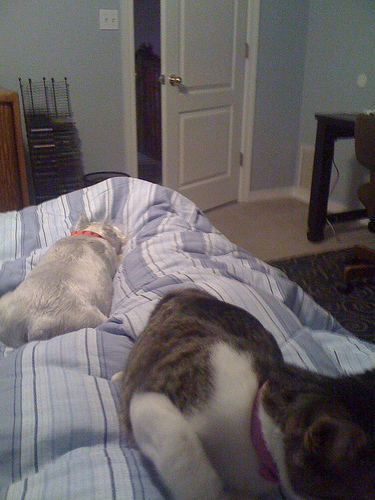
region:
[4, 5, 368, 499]
Interior view, season, not known.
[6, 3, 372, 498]
Room interior, likely daytime, with natural light.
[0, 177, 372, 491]
Bedding with striped coverlet.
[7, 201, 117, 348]
Reclining light grey and white cat.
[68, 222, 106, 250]
Pink collar on cat.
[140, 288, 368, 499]
Prone dark grey and white cat.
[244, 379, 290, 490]
Lavender collar on cat.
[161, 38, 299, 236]
Blue wall, next to white door and baseboard with vent.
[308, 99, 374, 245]
Small balck table, with chair and electrical cord.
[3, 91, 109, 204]
Part of wood furnishing and metal rack with items on it.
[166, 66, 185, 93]
gld colored door knob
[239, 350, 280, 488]
purple collar on a cat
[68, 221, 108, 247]
orange collar on a cat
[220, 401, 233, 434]
white fur ona cat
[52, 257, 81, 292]
grey fur on a cat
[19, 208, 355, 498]
two cats laying on the bed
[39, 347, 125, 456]
blue striped bed spread cover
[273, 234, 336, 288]
area rug on the bedroom floor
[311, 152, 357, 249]
wires by a night stand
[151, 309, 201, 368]
back of a tabby cat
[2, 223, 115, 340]
a cat on the bed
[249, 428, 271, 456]
a purple collar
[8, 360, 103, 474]
the comforter is blue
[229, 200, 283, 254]
the carpet is brown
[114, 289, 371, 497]
the cat is grey and white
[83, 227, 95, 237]
a black and red collar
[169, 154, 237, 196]
a white door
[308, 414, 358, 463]
ear on the cat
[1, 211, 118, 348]
the cat is lying on the bed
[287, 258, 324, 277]
a rug on the floor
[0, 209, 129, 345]
a dog laying on a bed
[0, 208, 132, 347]
a dog sleeping on a blanket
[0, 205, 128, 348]
a dog with a red and black collar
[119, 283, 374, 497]
a cat laying on a blanket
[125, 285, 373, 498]
a cat sleeping on a bed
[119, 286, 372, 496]
a cat with a purple collar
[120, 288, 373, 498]
a black and white cat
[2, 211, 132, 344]
a white and gray dog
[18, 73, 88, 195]
a rack of cds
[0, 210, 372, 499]
two animals laying on a bed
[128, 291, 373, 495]
gray and white cat with purple collar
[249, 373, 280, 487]
purple collar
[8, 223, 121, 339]
light gray cat with orange collar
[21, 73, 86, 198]
black metal DVD rack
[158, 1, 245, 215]
white bedroom door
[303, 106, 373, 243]
corner of a black desk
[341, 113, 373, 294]
brown desk chair with wheels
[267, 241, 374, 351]
dark-colored area rug under the chair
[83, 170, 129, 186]
top of a black wire trash can